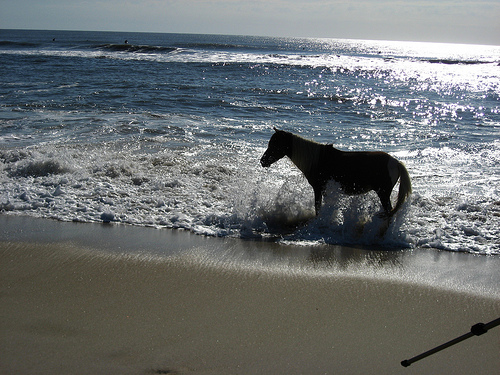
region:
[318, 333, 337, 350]
the sand is black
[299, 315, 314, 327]
the sand is black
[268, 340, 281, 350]
the sand is black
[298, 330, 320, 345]
the sand is black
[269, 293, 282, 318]
the sand is black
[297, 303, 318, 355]
the sand is black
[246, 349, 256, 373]
the sand is black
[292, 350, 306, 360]
the sand is black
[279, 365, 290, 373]
the sand is black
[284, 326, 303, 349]
the sand is black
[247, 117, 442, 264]
Horse with long tail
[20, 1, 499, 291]
Blue ocean with white waves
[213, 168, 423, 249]
Wave crashing against shore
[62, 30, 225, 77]
Rocky outcropping in ocean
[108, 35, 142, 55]
Seabird sitting on rocky outcropping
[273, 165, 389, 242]
Waves breaking against horse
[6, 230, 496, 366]
Tan sandy beach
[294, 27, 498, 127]
Bright sun reflecting off water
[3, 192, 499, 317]
Sand saturated in seawater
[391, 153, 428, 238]
Swishing horse tail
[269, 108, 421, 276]
the horse is wet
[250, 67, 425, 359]
the horse is wet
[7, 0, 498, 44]
a mild sky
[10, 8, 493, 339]
a scene near the beach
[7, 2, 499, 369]
a scene outside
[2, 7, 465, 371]
scene that is happening during the day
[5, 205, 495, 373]
a sandy shoreline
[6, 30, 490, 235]
a blue and white beach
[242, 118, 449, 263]
a horse in the water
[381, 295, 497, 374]
a shadow of an object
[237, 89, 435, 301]
an animal splashing in the water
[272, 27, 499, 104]
reflection of sun on the water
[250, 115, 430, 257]
horse walking through the water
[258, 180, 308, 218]
water splashing up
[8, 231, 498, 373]
tan sand that is slightly wet from the waves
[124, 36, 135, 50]
person in the water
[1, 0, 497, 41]
clear sky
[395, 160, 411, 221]
long and dark horse tail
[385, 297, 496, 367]
dark shadow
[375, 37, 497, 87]
sun reflecting on the water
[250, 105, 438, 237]
dark horse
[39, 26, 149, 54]
two people in the water